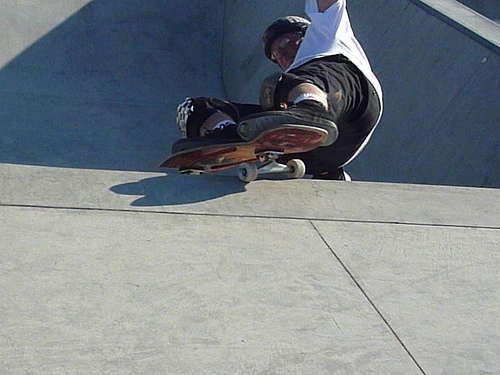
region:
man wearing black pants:
[330, 68, 348, 85]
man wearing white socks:
[304, 92, 321, 100]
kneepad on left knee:
[173, 98, 205, 126]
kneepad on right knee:
[261, 75, 288, 99]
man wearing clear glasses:
[268, 36, 297, 46]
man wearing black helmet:
[268, 22, 291, 29]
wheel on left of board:
[236, 163, 258, 182]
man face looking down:
[254, 24, 308, 70]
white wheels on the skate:
[211, 156, 324, 189]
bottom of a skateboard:
[172, 136, 317, 163]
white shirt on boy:
[305, 11, 387, 63]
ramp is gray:
[5, 194, 480, 373]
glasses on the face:
[251, 36, 301, 56]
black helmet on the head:
[247, 10, 304, 30]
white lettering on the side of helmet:
[273, 14, 308, 21]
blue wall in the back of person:
[7, 14, 171, 158]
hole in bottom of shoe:
[237, 119, 251, 143]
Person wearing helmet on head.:
[256, 16, 303, 43]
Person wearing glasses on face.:
[260, 42, 295, 57]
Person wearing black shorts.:
[322, 64, 354, 94]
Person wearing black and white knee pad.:
[166, 91, 211, 137]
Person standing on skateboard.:
[171, 115, 329, 167]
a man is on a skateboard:
[158, 1, 383, 184]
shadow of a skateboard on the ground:
[108, 169, 299, 208]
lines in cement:
[0, 200, 498, 373]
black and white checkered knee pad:
[174, 95, 194, 135]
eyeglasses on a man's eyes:
[268, 30, 305, 60]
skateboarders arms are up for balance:
[158, 1, 383, 183]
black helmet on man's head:
[259, 13, 311, 63]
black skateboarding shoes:
[169, 98, 340, 154]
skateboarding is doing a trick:
[158, 1, 383, 186]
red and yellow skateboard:
[158, 121, 329, 179]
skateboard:
[148, 120, 393, 252]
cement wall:
[97, 241, 249, 320]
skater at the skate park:
[1, 0, 402, 205]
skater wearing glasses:
[242, 12, 324, 61]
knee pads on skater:
[140, 74, 332, 136]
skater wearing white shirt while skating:
[242, 0, 414, 185]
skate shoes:
[232, 90, 377, 160]